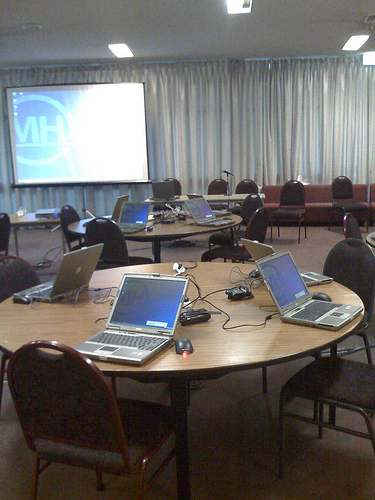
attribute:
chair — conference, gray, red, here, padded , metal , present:
[28, 331, 156, 477]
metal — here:
[72, 367, 163, 469]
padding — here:
[42, 351, 123, 456]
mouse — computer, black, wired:
[177, 294, 251, 346]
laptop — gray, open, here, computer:
[97, 269, 193, 393]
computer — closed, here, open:
[53, 250, 193, 368]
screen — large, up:
[27, 89, 151, 183]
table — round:
[43, 278, 230, 372]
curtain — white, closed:
[146, 86, 315, 170]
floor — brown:
[210, 411, 304, 478]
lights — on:
[97, 19, 345, 49]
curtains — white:
[157, 83, 332, 221]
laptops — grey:
[49, 232, 257, 328]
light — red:
[166, 335, 210, 353]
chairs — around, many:
[182, 170, 360, 242]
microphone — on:
[24, 185, 114, 236]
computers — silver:
[51, 187, 269, 248]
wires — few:
[163, 262, 297, 357]